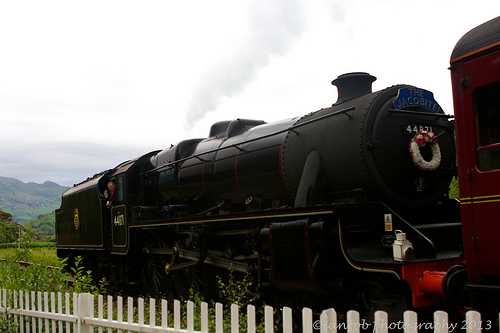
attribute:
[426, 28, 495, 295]
train car — red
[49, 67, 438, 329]
wagon — long, boiler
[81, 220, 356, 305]
line — black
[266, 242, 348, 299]
wheel — train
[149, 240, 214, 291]
wheel — train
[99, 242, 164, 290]
wheel — train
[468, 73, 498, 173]
window — train carriage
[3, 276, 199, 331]
fence — picket, white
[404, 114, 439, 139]
numbers — white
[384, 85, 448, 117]
poster letterhead — blue, metal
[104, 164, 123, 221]
window — train carriage, drive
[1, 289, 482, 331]
fence — white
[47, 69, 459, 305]
wagon — chimney top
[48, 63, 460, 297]
train — black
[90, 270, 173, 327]
fence — white 